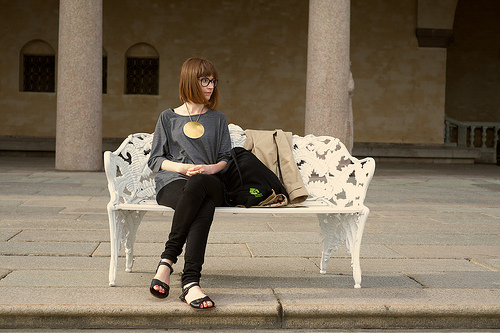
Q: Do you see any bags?
A: Yes, there is a bag.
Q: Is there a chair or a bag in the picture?
A: Yes, there is a bag.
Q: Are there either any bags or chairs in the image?
A: Yes, there is a bag.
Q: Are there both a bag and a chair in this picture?
A: No, there is a bag but no chairs.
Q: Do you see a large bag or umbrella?
A: Yes, there is a large bag.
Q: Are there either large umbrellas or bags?
A: Yes, there is a large bag.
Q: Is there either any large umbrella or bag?
A: Yes, there is a large bag.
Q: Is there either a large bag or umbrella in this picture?
A: Yes, there is a large bag.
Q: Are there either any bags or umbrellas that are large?
A: Yes, the bag is large.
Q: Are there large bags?
A: Yes, there is a large bag.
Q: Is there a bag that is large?
A: Yes, there is a bag that is large.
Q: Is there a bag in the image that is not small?
A: Yes, there is a large bag.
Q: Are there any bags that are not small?
A: Yes, there is a large bag.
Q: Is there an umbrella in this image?
A: No, there are no umbrellas.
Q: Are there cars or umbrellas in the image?
A: No, there are no umbrellas or cars.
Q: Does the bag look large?
A: Yes, the bag is large.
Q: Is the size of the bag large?
A: Yes, the bag is large.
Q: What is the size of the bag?
A: The bag is large.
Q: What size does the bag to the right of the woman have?
A: The bag has large size.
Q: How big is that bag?
A: The bag is large.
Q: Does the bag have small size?
A: No, the bag is large.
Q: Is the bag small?
A: No, the bag is large.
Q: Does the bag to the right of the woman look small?
A: No, the bag is large.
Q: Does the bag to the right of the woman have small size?
A: No, the bag is large.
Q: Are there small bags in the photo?
A: No, there is a bag but it is large.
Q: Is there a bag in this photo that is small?
A: No, there is a bag but it is large.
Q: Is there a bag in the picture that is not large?
A: No, there is a bag but it is large.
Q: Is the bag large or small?
A: The bag is large.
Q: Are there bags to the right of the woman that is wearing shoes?
A: Yes, there is a bag to the right of the woman.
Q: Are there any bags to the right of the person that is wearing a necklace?
A: Yes, there is a bag to the right of the woman.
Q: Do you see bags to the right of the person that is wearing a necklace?
A: Yes, there is a bag to the right of the woman.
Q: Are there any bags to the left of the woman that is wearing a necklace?
A: No, the bag is to the right of the woman.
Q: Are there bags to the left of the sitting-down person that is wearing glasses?
A: No, the bag is to the right of the woman.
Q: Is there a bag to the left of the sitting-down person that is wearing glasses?
A: No, the bag is to the right of the woman.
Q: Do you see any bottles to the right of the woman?
A: No, there is a bag to the right of the woman.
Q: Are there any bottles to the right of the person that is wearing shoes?
A: No, there is a bag to the right of the woman.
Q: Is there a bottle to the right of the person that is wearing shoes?
A: No, there is a bag to the right of the woman.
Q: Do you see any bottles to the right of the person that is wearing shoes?
A: No, there is a bag to the right of the woman.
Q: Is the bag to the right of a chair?
A: No, the bag is to the right of a woman.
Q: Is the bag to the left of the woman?
A: No, the bag is to the right of the woman.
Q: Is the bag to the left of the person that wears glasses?
A: No, the bag is to the right of the woman.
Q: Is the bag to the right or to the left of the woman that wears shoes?
A: The bag is to the right of the woman.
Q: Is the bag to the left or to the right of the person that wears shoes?
A: The bag is to the right of the woman.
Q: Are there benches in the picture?
A: Yes, there is a bench.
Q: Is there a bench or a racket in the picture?
A: Yes, there is a bench.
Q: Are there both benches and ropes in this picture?
A: No, there is a bench but no ropes.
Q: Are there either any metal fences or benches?
A: Yes, there is a metal bench.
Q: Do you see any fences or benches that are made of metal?
A: Yes, the bench is made of metal.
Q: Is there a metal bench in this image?
A: Yes, there is a metal bench.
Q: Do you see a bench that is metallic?
A: Yes, there is a bench that is metallic.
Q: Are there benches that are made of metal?
A: Yes, there is a bench that is made of metal.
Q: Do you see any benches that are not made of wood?
A: Yes, there is a bench that is made of metal.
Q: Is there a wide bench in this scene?
A: Yes, there is a wide bench.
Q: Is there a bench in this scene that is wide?
A: Yes, there is a bench that is wide.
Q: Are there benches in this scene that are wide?
A: Yes, there is a bench that is wide.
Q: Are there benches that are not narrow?
A: Yes, there is a wide bench.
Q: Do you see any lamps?
A: No, there are no lamps.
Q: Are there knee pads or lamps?
A: No, there are no lamps or knee pads.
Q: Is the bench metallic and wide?
A: Yes, the bench is metallic and wide.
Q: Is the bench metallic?
A: Yes, the bench is metallic.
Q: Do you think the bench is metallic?
A: Yes, the bench is metallic.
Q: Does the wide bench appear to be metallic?
A: Yes, the bench is metallic.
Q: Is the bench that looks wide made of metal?
A: Yes, the bench is made of metal.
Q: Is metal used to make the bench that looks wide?
A: Yes, the bench is made of metal.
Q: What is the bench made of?
A: The bench is made of metal.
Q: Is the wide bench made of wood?
A: No, the bench is made of metal.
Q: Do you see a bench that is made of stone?
A: No, there is a bench but it is made of metal.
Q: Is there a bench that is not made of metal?
A: No, there is a bench but it is made of metal.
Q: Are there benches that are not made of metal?
A: No, there is a bench but it is made of metal.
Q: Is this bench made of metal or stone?
A: The bench is made of metal.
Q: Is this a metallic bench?
A: Yes, this is a metallic bench.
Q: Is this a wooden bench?
A: No, this is a metallic bench.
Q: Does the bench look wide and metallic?
A: Yes, the bench is wide and metallic.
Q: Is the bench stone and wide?
A: No, the bench is wide but metallic.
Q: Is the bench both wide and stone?
A: No, the bench is wide but metallic.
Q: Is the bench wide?
A: Yes, the bench is wide.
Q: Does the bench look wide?
A: Yes, the bench is wide.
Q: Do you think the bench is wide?
A: Yes, the bench is wide.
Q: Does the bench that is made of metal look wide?
A: Yes, the bench is wide.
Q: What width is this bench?
A: The bench is wide.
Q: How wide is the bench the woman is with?
A: The bench is wide.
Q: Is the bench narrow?
A: No, the bench is wide.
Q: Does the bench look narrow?
A: No, the bench is wide.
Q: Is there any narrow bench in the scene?
A: No, there is a bench but it is wide.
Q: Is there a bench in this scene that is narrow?
A: No, there is a bench but it is wide.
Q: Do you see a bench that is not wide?
A: No, there is a bench but it is wide.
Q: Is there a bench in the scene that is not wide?
A: No, there is a bench but it is wide.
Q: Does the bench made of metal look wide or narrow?
A: The bench is wide.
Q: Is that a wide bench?
A: Yes, that is a wide bench.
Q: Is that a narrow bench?
A: No, that is a wide bench.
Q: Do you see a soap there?
A: No, there are no soaps.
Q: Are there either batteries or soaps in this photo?
A: No, there are no soaps or batteries.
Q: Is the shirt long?
A: Yes, the shirt is long.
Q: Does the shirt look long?
A: Yes, the shirt is long.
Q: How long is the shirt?
A: The shirt is long.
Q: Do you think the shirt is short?
A: No, the shirt is long.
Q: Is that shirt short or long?
A: The shirt is long.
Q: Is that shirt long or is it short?
A: The shirt is long.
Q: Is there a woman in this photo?
A: Yes, there is a woman.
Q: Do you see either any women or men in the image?
A: Yes, there is a woman.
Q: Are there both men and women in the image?
A: No, there is a woman but no men.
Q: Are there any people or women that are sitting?
A: Yes, the woman is sitting.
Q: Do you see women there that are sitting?
A: Yes, there is a woman that is sitting.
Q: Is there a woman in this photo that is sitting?
A: Yes, there is a woman that is sitting.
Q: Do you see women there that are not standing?
A: Yes, there is a woman that is sitting .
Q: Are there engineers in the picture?
A: No, there are no engineers.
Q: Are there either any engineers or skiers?
A: No, there are no engineers or skiers.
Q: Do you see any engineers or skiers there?
A: No, there are no engineers or skiers.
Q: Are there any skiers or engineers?
A: No, there are no engineers or skiers.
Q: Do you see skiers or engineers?
A: No, there are no engineers or skiers.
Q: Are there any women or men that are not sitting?
A: No, there is a woman but she is sitting.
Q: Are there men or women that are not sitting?
A: No, there is a woman but she is sitting.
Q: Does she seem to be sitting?
A: Yes, the woman is sitting.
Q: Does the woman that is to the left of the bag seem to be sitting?
A: Yes, the woman is sitting.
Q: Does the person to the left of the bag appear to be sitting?
A: Yes, the woman is sitting.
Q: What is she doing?
A: The woman is sitting.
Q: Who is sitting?
A: The woman is sitting.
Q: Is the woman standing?
A: No, the woman is sitting.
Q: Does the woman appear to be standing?
A: No, the woman is sitting.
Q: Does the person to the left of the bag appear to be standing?
A: No, the woman is sitting.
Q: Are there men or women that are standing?
A: No, there is a woman but she is sitting.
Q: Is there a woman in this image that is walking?
A: No, there is a woman but she is sitting.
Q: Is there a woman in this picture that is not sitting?
A: No, there is a woman but she is sitting.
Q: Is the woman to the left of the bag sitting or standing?
A: The woman is sitting.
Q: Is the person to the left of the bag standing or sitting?
A: The woman is sitting.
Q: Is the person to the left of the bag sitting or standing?
A: The woman is sitting.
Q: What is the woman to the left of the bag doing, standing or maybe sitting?
A: The woman is sitting.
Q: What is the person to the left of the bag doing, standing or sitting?
A: The woman is sitting.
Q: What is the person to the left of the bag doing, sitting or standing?
A: The woman is sitting.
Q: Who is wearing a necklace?
A: The woman is wearing a necklace.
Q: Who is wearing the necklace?
A: The woman is wearing a necklace.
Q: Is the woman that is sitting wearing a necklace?
A: Yes, the woman is wearing a necklace.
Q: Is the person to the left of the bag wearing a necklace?
A: Yes, the woman is wearing a necklace.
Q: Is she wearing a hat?
A: No, the woman is wearing a necklace.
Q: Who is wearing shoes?
A: The woman is wearing shoes.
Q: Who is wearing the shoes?
A: The woman is wearing shoes.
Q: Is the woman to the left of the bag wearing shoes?
A: Yes, the woman is wearing shoes.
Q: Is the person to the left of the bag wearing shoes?
A: Yes, the woman is wearing shoes.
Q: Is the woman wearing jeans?
A: No, the woman is wearing shoes.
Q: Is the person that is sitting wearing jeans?
A: No, the woman is wearing shoes.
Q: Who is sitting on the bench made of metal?
A: The woman is sitting on the bench.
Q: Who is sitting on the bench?
A: The woman is sitting on the bench.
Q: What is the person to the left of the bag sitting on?
A: The woman is sitting on the bench.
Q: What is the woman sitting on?
A: The woman is sitting on the bench.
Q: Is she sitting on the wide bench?
A: Yes, the woman is sitting on the bench.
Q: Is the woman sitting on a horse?
A: No, the woman is sitting on the bench.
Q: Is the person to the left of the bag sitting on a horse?
A: No, the woman is sitting on the bench.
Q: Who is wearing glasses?
A: The woman is wearing glasses.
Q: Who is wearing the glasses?
A: The woman is wearing glasses.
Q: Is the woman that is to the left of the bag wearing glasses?
A: Yes, the woman is wearing glasses.